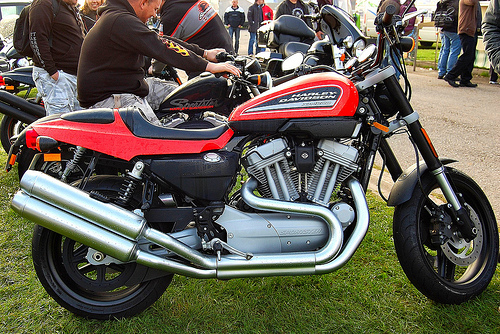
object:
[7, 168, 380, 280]
pipe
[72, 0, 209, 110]
shirt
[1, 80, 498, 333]
grass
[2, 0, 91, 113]
man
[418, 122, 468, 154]
ground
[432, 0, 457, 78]
people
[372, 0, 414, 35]
people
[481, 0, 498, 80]
people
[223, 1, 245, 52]
people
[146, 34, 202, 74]
sleeve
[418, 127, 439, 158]
light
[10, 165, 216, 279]
exhaust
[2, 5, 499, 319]
bike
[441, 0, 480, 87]
people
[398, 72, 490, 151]
street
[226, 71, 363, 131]
tank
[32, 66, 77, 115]
pants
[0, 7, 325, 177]
bike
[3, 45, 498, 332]
ground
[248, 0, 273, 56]
person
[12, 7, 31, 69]
backpack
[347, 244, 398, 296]
part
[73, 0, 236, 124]
he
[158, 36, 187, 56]
logo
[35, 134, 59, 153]
light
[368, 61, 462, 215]
road